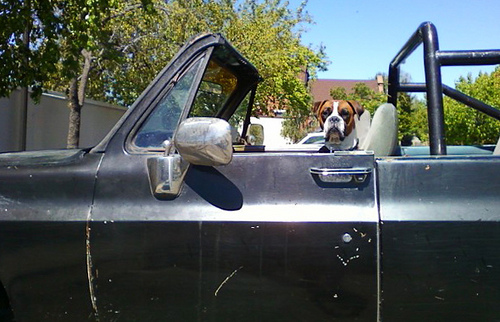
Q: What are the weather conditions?
A: It is clear.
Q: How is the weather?
A: It is clear.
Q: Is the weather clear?
A: Yes, it is clear.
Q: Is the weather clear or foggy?
A: It is clear.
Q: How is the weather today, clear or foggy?
A: It is clear.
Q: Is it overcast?
A: No, it is clear.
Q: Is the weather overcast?
A: No, it is clear.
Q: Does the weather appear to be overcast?
A: No, it is clear.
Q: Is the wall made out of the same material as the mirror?
A: No, the wall is made of cement and the mirror is made of metal.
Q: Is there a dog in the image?
A: Yes, there is a dog.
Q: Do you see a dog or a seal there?
A: Yes, there is a dog.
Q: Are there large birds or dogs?
A: Yes, there is a large dog.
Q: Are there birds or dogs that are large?
A: Yes, the dog is large.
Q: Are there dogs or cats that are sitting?
A: Yes, the dog is sitting.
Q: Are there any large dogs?
A: Yes, there is a large dog.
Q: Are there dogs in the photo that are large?
A: Yes, there is a dog that is large.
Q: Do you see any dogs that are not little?
A: Yes, there is a large dog.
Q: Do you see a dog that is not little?
A: Yes, there is a large dog.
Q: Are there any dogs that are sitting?
A: Yes, there is a dog that is sitting.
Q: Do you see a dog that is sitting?
A: Yes, there is a dog that is sitting.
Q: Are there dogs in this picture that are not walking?
A: Yes, there is a dog that is sitting.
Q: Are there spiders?
A: No, there are no spiders.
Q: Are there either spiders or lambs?
A: No, there are no spiders or lambs.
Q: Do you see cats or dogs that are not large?
A: No, there is a dog but it is large.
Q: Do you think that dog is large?
A: Yes, the dog is large.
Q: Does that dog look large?
A: Yes, the dog is large.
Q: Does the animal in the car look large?
A: Yes, the dog is large.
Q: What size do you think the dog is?
A: The dog is large.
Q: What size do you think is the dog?
A: The dog is large.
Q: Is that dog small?
A: No, the dog is large.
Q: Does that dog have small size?
A: No, the dog is large.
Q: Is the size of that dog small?
A: No, the dog is large.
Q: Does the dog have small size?
A: No, the dog is large.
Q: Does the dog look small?
A: No, the dog is large.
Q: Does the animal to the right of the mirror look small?
A: No, the dog is large.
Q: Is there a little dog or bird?
A: No, there is a dog but it is large.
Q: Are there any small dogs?
A: No, there is a dog but it is large.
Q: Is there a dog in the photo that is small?
A: No, there is a dog but it is large.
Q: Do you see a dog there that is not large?
A: No, there is a dog but it is large.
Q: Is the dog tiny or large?
A: The dog is large.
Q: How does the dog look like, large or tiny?
A: The dog is large.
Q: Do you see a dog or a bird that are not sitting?
A: No, there is a dog but it is sitting.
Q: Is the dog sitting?
A: Yes, the dog is sitting.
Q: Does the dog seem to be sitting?
A: Yes, the dog is sitting.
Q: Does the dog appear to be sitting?
A: Yes, the dog is sitting.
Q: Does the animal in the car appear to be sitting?
A: Yes, the dog is sitting.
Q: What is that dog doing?
A: The dog is sitting.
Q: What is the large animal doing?
A: The dog is sitting.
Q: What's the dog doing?
A: The dog is sitting.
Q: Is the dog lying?
A: No, the dog is sitting.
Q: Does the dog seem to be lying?
A: No, the dog is sitting.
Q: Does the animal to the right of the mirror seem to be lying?
A: No, the dog is sitting.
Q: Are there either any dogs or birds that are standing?
A: No, there is a dog but it is sitting.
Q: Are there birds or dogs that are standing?
A: No, there is a dog but it is sitting.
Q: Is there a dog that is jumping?
A: No, there is a dog but it is sitting.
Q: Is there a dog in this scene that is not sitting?
A: No, there is a dog but it is sitting.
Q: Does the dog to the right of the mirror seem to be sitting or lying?
A: The dog is sitting.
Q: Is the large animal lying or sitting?
A: The dog is sitting.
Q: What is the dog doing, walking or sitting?
A: The dog is sitting.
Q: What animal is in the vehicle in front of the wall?
A: The dog is in the car.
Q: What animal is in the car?
A: The dog is in the car.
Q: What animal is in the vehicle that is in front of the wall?
A: The animal is a dog.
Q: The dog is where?
A: The dog is in the car.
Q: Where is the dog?
A: The dog is in the car.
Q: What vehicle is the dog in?
A: The dog is in the car.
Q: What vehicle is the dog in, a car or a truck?
A: The dog is in a car.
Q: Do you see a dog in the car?
A: Yes, there is a dog in the car.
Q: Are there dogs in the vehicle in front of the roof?
A: Yes, there is a dog in the car.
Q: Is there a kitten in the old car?
A: No, there is a dog in the car.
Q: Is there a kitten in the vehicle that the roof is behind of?
A: No, there is a dog in the car.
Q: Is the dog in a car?
A: Yes, the dog is in a car.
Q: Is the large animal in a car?
A: Yes, the dog is in a car.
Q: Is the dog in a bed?
A: No, the dog is in a car.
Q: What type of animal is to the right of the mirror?
A: The animal is a dog.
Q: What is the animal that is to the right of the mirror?
A: The animal is a dog.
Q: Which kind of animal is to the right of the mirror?
A: The animal is a dog.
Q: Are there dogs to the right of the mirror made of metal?
A: Yes, there is a dog to the right of the mirror.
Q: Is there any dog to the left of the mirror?
A: No, the dog is to the right of the mirror.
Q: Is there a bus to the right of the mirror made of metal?
A: No, there is a dog to the right of the mirror.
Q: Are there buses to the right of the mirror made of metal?
A: No, there is a dog to the right of the mirror.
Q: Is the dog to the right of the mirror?
A: Yes, the dog is to the right of the mirror.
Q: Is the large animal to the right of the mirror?
A: Yes, the dog is to the right of the mirror.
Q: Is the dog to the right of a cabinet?
A: No, the dog is to the right of the mirror.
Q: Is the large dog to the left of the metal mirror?
A: No, the dog is to the right of the mirror.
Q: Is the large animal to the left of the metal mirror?
A: No, the dog is to the right of the mirror.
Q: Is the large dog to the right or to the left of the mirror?
A: The dog is to the right of the mirror.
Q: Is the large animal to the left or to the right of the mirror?
A: The dog is to the right of the mirror.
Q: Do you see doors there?
A: Yes, there is a door.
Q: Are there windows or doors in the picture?
A: Yes, there is a door.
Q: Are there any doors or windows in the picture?
A: Yes, there is a door.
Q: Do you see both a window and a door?
A: Yes, there are both a door and a window.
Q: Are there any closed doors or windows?
A: Yes, there is a closed door.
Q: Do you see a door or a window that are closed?
A: Yes, the door is closed.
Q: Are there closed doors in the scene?
A: Yes, there is a closed door.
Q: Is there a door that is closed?
A: Yes, there is a door that is closed.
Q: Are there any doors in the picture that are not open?
A: Yes, there is an closed door.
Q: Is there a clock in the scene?
A: No, there are no clocks.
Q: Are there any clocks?
A: No, there are no clocks.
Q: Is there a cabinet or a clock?
A: No, there are no clocks or cabinets.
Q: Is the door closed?
A: Yes, the door is closed.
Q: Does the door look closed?
A: Yes, the door is closed.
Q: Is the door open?
A: No, the door is closed.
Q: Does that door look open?
A: No, the door is closed.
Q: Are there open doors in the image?
A: No, there is a door but it is closed.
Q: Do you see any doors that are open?
A: No, there is a door but it is closed.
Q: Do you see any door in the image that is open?
A: No, there is a door but it is closed.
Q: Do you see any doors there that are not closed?
A: No, there is a door but it is closed.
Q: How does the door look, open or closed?
A: The door is closed.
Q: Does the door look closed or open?
A: The door is closed.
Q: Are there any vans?
A: No, there are no vans.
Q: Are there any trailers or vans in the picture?
A: No, there are no vans or trailers.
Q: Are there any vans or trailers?
A: No, there are no vans or trailers.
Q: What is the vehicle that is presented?
A: The vehicle is a car.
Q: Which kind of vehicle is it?
A: The vehicle is a car.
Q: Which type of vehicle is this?
A: This is a car.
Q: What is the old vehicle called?
A: The vehicle is a car.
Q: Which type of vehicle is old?
A: The vehicle is a car.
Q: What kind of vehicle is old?
A: The vehicle is a car.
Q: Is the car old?
A: Yes, the car is old.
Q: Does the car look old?
A: Yes, the car is old.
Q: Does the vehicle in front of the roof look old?
A: Yes, the car is old.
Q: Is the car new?
A: No, the car is old.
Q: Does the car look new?
A: No, the car is old.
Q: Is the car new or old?
A: The car is old.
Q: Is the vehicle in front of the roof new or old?
A: The car is old.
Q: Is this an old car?
A: Yes, this is an old car.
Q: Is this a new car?
A: No, this is an old car.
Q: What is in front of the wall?
A: The car is in front of the wall.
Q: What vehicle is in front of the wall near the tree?
A: The vehicle is a car.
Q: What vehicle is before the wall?
A: The vehicle is a car.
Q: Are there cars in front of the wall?
A: Yes, there is a car in front of the wall.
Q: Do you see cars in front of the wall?
A: Yes, there is a car in front of the wall.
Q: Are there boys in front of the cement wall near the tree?
A: No, there is a car in front of the wall.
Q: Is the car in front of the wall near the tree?
A: Yes, the car is in front of the wall.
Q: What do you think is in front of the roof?
A: The car is in front of the roof.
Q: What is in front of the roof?
A: The car is in front of the roof.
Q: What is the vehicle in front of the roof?
A: The vehicle is a car.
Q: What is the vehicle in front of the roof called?
A: The vehicle is a car.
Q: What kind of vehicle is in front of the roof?
A: The vehicle is a car.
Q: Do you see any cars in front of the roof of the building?
A: Yes, there is a car in front of the roof.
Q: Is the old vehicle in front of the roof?
A: Yes, the car is in front of the roof.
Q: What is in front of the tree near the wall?
A: The car is in front of the tree.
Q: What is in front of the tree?
A: The car is in front of the tree.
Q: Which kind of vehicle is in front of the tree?
A: The vehicle is a car.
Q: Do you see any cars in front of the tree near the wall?
A: Yes, there is a car in front of the tree.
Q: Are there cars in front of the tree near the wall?
A: Yes, there is a car in front of the tree.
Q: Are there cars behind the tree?
A: No, the car is in front of the tree.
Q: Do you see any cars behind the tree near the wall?
A: No, the car is in front of the tree.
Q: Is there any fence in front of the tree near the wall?
A: No, there is a car in front of the tree.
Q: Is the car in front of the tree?
A: Yes, the car is in front of the tree.